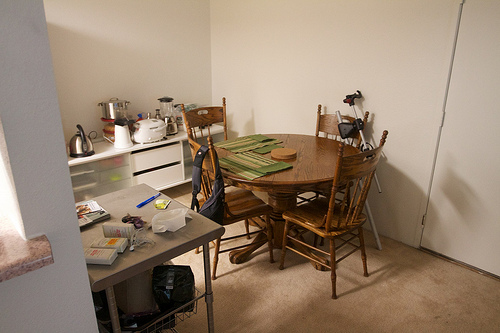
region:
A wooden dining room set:
[178, 103, 387, 297]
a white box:
[84, 248, 116, 264]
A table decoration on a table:
[269, 147, 296, 160]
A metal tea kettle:
[66, 124, 93, 156]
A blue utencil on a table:
[137, 190, 160, 207]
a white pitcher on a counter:
[112, 116, 133, 146]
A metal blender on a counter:
[159, 96, 176, 134]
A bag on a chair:
[187, 145, 227, 221]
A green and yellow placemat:
[217, 150, 292, 179]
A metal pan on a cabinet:
[97, 96, 129, 121]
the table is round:
[216, 121, 333, 180]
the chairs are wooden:
[200, 130, 387, 233]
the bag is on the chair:
[180, 142, 239, 224]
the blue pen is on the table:
[131, 182, 164, 210]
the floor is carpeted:
[244, 280, 330, 317]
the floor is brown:
[251, 287, 310, 322]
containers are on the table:
[91, 225, 128, 266]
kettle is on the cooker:
[63, 124, 104, 162]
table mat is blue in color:
[228, 141, 281, 178]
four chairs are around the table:
[176, 93, 386, 254]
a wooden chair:
[301, 152, 380, 281]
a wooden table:
[201, 129, 358, 260]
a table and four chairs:
[183, 100, 380, 286]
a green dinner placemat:
[228, 148, 279, 177]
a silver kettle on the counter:
[71, 128, 97, 151]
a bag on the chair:
[191, 150, 227, 224]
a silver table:
[83, 180, 240, 327]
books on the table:
[89, 216, 134, 263]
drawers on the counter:
[135, 137, 189, 187]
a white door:
[428, 23, 492, 272]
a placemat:
[229, 148, 269, 185]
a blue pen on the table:
[133, 193, 153, 206]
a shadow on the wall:
[394, 189, 431, 236]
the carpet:
[372, 282, 450, 325]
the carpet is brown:
[327, 305, 401, 330]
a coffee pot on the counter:
[63, 125, 99, 155]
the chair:
[176, 100, 226, 122]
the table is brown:
[303, 134, 326, 174]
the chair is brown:
[332, 144, 389, 179]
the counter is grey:
[115, 192, 132, 207]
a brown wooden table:
[204, 115, 369, 205]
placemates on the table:
[218, 125, 299, 212]